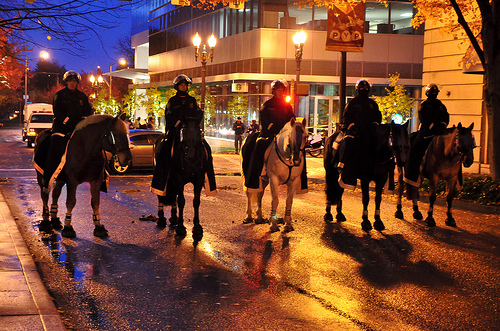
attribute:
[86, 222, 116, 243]
hoof — black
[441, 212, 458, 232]
hoof — black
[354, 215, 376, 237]
hoof — black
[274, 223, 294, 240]
hoof — black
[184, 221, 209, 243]
hoof — black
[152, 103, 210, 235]
horse — black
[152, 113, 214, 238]
horse — walking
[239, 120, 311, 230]
horse — walking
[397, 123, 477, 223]
horse — walking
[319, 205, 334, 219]
hoof — Black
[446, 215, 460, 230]
hoof — black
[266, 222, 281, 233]
hoof — black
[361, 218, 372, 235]
hoof — black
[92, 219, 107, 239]
hoof — black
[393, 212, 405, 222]
hoof — black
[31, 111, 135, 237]
horse — walking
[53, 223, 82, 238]
hoof — black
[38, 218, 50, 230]
hoof — black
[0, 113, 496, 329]
street — Wet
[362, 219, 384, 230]
hoof — black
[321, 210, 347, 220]
hoof — black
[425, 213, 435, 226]
hoof — black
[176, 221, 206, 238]
hoof — black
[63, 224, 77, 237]
hoof — black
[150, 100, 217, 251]
horse — black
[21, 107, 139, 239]
horse — walking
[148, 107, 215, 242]
horse — walking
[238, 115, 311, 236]
horse — walking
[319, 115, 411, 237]
horse — walking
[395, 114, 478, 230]
horse — walking